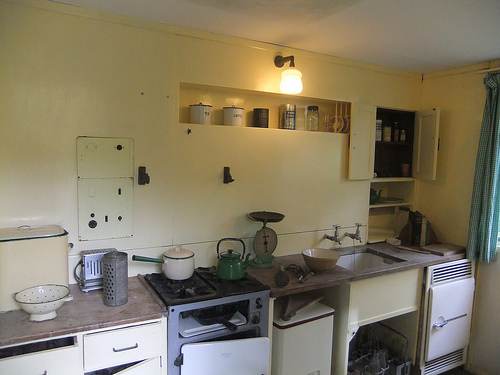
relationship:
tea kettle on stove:
[212, 237, 252, 281] [165, 279, 275, 369]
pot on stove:
[132, 245, 194, 280] [139, 262, 270, 373]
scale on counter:
[247, 211, 284, 271] [242, 253, 350, 296]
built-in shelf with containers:
[163, 77, 352, 138] [188, 92, 214, 123]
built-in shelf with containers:
[163, 77, 352, 138] [221, 99, 245, 124]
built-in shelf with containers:
[163, 77, 352, 138] [251, 102, 271, 129]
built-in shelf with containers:
[163, 77, 352, 138] [278, 98, 300, 130]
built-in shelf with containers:
[163, 77, 352, 138] [303, 99, 326, 129]